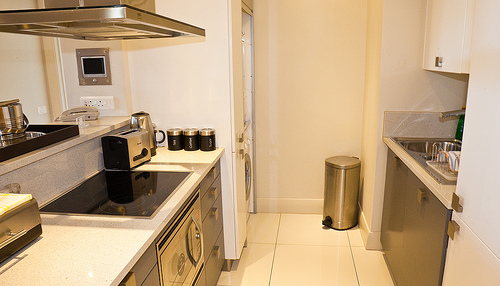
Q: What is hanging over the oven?
A: A fan.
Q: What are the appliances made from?
A: Stainless steel.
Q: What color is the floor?
A: White.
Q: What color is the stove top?
A: Black.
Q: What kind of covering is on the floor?
A: Tiles.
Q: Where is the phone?
A: On a shelf behind the counter.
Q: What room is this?
A: The kitchen.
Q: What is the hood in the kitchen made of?
A: Stainless steel.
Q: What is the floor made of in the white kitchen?
A: White tile.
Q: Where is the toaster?
A: On the counter.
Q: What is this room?
A: A kitchen.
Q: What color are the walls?
A: White.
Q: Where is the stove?
A: On the left side.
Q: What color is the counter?
A: White.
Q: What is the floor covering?
A: Tiles.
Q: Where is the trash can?
A: In the corner.